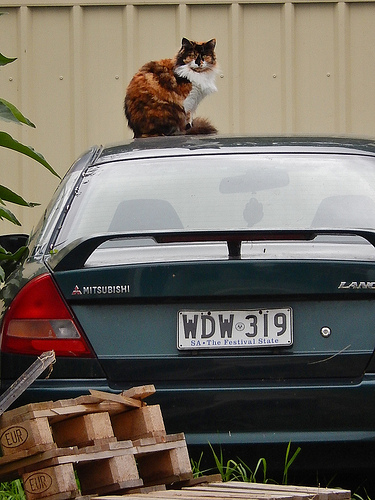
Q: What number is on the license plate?
A: 319.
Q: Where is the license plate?
A: On the car.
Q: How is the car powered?
A: Fuel.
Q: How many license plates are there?
A: One.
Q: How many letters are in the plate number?
A: W and D.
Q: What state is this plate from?
A: The festival state.